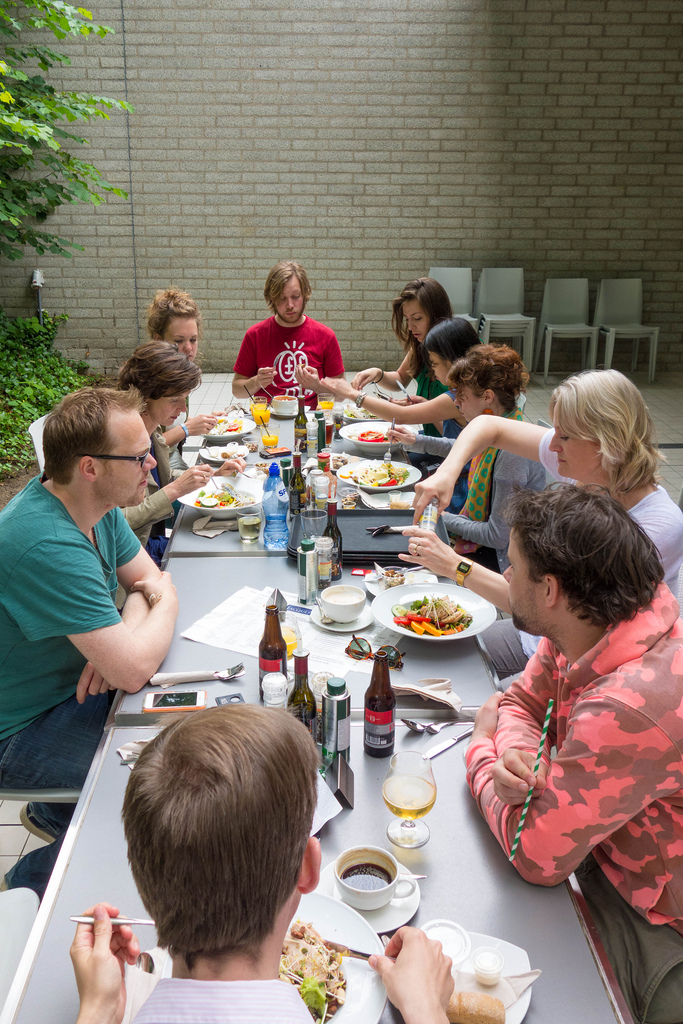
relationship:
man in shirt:
[232, 258, 350, 414] [234, 319, 344, 403]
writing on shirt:
[272, 343, 317, 397] [234, 319, 344, 403]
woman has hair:
[410, 372, 680, 604] [548, 367, 662, 488]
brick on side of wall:
[401, 228, 432, 237] [1, 59, 680, 369]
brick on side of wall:
[329, 182, 366, 193] [1, 59, 680, 369]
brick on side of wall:
[405, 163, 436, 174] [1, 59, 680, 369]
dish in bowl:
[391, 591, 473, 637] [369, 581, 496, 645]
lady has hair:
[358, 279, 457, 431] [395, 280, 447, 343]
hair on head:
[514, 489, 663, 616] [492, 493, 659, 649]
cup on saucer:
[334, 848, 414, 915] [310, 851, 419, 935]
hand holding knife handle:
[371, 936, 460, 1019] [318, 936, 393, 962]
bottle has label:
[360, 651, 396, 756] [360, 709, 393, 753]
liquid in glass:
[381, 773, 431, 813] [383, 753, 438, 852]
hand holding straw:
[489, 748, 549, 801] [507, 690, 555, 866]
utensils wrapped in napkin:
[143, 664, 247, 685] [148, 673, 217, 684]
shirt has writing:
[234, 319, 344, 403] [271, 340, 316, 401]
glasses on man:
[88, 437, 153, 475] [15, 387, 176, 675]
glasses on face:
[88, 437, 153, 475] [48, 410, 163, 508]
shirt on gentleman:
[0, 493, 120, 722] [0, 384, 181, 914]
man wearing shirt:
[238, 266, 342, 402] [241, 317, 335, 400]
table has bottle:
[0, 404, 637, 1022] [287, 450, 308, 514]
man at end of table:
[232, 258, 350, 414] [0, 404, 637, 1022]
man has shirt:
[232, 258, 350, 414] [230, 313, 349, 409]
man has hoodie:
[462, 482, 680, 1022] [463, 573, 683, 937]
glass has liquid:
[378, 749, 438, 850] [381, 774, 437, 823]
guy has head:
[66, 699, 457, 1023] [122, 701, 323, 958]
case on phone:
[146, 692, 201, 715] [141, 686, 209, 712]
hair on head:
[133, 278, 206, 348] [137, 281, 206, 381]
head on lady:
[137, 281, 206, 381] [121, 271, 236, 459]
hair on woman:
[539, 360, 676, 495] [396, 365, 682, 704]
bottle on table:
[252, 460, 295, 556] [0, 404, 637, 1022]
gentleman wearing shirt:
[3, 379, 189, 847] [3, 473, 152, 741]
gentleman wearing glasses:
[3, 379, 189, 847] [83, 453, 158, 467]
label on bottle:
[363, 702, 396, 754] [353, 644, 397, 763]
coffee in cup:
[338, 863, 396, 896] [333, 844, 417, 913]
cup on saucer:
[333, 844, 417, 913] [312, 849, 434, 944]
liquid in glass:
[381, 774, 437, 823] [374, 751, 442, 859]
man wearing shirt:
[232, 258, 350, 414] [225, 307, 351, 408]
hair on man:
[499, 482, 666, 631] [462, 482, 680, 1022]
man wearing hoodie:
[462, 482, 680, 1022] [463, 573, 683, 937]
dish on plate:
[383, 603, 453, 646] [364, 568, 500, 654]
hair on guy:
[118, 697, 322, 979] [50, 700, 463, 1022]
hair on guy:
[118, 692, 329, 985] [50, 700, 463, 1022]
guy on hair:
[50, 700, 463, 1022] [118, 697, 322, 979]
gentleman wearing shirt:
[0, 384, 181, 914] [0, 470, 143, 746]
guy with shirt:
[66, 699, 457, 1023] [126, 972, 328, 1020]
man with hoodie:
[463, 476, 679, 1024] [468, 583, 680, 934]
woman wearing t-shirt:
[396, 365, 682, 704] [538, 427, 682, 605]